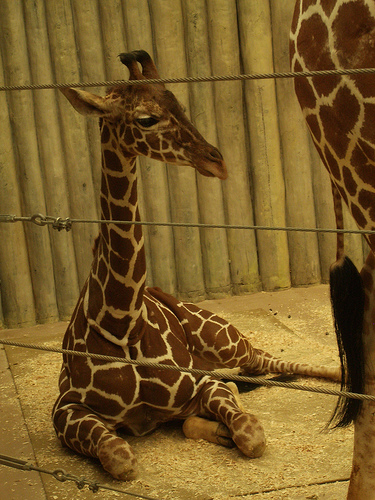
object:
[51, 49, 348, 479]
giraffe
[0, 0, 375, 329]
fence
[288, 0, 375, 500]
giraffe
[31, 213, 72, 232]
hook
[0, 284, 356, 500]
ground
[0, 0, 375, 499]
picture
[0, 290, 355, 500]
sawdust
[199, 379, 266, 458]
legs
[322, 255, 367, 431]
fur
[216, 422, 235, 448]
foot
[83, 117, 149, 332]
neck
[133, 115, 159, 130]
eye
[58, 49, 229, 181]
head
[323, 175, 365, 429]
tail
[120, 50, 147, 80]
ossicles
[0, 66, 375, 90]
poles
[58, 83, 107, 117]
ear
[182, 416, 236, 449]
leg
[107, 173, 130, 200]
spot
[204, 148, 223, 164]
nostril